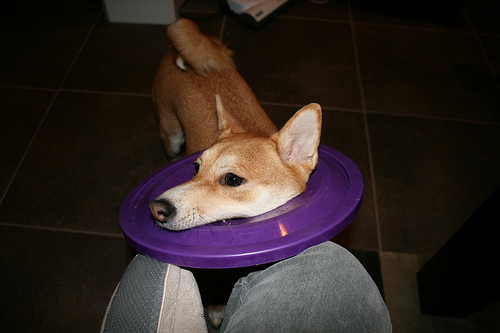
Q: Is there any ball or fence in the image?
A: No, there are no fences or balls.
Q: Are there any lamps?
A: No, there are no lamps.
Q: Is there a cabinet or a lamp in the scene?
A: No, there are no lamps or cabinets.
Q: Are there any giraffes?
A: No, there are no giraffes.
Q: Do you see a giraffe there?
A: No, there are no giraffes.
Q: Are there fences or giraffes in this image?
A: No, there are no giraffes or fences.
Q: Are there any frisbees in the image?
A: Yes, there is a frisbee.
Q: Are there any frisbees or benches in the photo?
A: Yes, there is a frisbee.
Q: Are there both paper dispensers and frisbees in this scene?
A: No, there is a frisbee but no paper dispensers.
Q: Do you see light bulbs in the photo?
A: No, there are no light bulbs.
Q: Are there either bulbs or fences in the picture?
A: No, there are no bulbs or fences.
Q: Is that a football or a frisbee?
A: That is a frisbee.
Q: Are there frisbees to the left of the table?
A: Yes, there is a frisbee to the left of the table.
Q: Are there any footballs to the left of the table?
A: No, there is a frisbee to the left of the table.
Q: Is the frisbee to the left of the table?
A: Yes, the frisbee is to the left of the table.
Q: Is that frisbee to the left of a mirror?
A: No, the frisbee is to the left of the table.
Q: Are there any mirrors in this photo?
A: No, there are no mirrors.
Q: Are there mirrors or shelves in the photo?
A: No, there are no mirrors or shelves.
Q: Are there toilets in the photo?
A: No, there are no toilets.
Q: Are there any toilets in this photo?
A: No, there are no toilets.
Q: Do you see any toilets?
A: No, there are no toilets.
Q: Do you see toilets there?
A: No, there are no toilets.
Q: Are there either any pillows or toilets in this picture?
A: No, there are no toilets or pillows.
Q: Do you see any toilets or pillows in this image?
A: No, there are no toilets or pillows.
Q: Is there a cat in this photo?
A: No, there are no cats.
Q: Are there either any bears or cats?
A: No, there are no cats or bears.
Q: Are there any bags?
A: No, there are no bags.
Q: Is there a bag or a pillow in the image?
A: No, there are no bags or pillows.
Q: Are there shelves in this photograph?
A: No, there are no shelves.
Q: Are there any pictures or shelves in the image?
A: No, there are no shelves or pictures.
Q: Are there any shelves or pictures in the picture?
A: No, there are no shelves or pictures.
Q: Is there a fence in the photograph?
A: No, there are no fences.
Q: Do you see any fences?
A: No, there are no fences.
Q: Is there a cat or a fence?
A: No, there are no fences or cats.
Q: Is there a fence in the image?
A: No, there are no fences.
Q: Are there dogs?
A: Yes, there is a dog.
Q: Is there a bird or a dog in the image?
A: Yes, there is a dog.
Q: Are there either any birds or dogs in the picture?
A: Yes, there is a dog.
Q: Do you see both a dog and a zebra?
A: No, there is a dog but no zebras.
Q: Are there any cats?
A: No, there are no cats.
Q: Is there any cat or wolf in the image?
A: No, there are no cats or wolves.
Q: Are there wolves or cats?
A: No, there are no cats or wolves.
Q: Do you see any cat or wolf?
A: No, there are no cats or wolves.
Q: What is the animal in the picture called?
A: The animal is a dog.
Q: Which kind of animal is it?
A: The animal is a dog.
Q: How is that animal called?
A: This is a dog.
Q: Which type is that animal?
A: This is a dog.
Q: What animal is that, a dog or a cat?
A: This is a dog.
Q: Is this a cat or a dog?
A: This is a dog.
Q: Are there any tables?
A: Yes, there is a table.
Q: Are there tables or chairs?
A: Yes, there is a table.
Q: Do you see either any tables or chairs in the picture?
A: Yes, there is a table.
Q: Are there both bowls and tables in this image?
A: No, there is a table but no bowls.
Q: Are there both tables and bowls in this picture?
A: No, there is a table but no bowls.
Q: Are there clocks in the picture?
A: No, there are no clocks.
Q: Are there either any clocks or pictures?
A: No, there are no clocks or pictures.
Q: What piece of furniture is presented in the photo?
A: The piece of furniture is a table.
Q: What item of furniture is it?
A: The piece of furniture is a table.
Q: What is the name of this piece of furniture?
A: That is a table.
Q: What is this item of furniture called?
A: That is a table.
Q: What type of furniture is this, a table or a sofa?
A: That is a table.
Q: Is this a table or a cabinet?
A: This is a table.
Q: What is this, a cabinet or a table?
A: This is a table.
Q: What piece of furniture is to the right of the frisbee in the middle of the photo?
A: The piece of furniture is a table.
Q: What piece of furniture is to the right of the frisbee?
A: The piece of furniture is a table.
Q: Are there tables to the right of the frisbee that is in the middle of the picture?
A: Yes, there is a table to the right of the frisbee.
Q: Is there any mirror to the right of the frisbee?
A: No, there is a table to the right of the frisbee.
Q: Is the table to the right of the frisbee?
A: Yes, the table is to the right of the frisbee.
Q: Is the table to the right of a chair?
A: No, the table is to the right of the frisbee.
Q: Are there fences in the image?
A: No, there are no fences.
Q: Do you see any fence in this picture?
A: No, there are no fences.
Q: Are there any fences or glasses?
A: No, there are no fences or glasses.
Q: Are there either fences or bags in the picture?
A: No, there are no bags or fences.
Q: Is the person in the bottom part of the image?
A: Yes, the person is in the bottom of the image.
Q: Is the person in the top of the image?
A: No, the person is in the bottom of the image.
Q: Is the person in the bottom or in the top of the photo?
A: The person is in the bottom of the image.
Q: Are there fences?
A: No, there are no fences.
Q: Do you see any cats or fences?
A: No, there are no fences or cats.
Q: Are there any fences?
A: No, there are no fences.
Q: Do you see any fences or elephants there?
A: No, there are no fences or elephants.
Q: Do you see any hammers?
A: No, there are no hammers.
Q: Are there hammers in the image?
A: No, there are no hammers.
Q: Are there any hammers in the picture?
A: No, there are no hammers.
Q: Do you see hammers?
A: No, there are no hammers.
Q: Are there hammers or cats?
A: No, there are no hammers or cats.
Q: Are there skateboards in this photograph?
A: No, there are no skateboards.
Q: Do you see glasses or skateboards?
A: No, there are no skateboards or glasses.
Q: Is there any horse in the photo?
A: No, there are no horses.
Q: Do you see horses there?
A: No, there are no horses.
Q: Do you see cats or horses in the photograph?
A: No, there are no horses or cats.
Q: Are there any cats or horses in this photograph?
A: No, there are no horses or cats.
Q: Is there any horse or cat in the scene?
A: No, there are no horses or cats.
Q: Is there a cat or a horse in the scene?
A: No, there are no horses or cats.